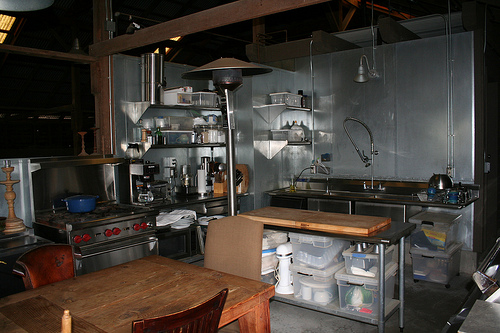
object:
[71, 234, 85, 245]
knobs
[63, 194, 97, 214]
pot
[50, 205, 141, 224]
stove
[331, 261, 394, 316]
containers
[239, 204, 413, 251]
counter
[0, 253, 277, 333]
table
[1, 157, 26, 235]
candle holder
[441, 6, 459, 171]
tubes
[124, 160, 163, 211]
coffee maker